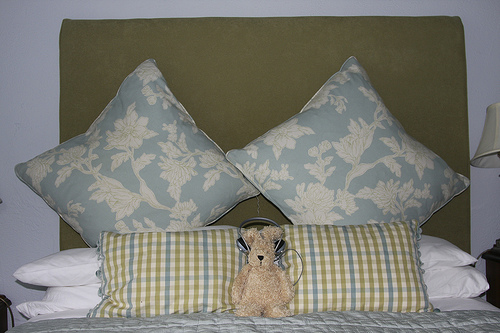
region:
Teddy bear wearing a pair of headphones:
[221, 210, 306, 322]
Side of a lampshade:
[462, 90, 499, 184]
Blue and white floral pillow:
[17, 63, 258, 267]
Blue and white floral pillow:
[217, 43, 481, 228]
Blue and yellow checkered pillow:
[94, 228, 429, 313]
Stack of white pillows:
[9, 249, 99, 327]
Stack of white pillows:
[419, 225, 495, 309]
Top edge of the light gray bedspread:
[0, 313, 498, 330]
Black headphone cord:
[280, 248, 317, 288]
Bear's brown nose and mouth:
[255, 251, 266, 265]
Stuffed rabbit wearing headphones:
[219, 212, 319, 328]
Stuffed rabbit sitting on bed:
[221, 210, 311, 330]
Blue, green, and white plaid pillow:
[113, 233, 226, 306]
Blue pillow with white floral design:
[287, 120, 416, 216]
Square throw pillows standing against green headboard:
[54, 18, 471, 223]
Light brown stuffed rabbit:
[228, 230, 298, 322]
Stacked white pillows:
[20, 249, 95, 316]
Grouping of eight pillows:
[12, 63, 497, 310]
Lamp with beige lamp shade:
[468, 104, 498, 169]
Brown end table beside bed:
[477, 242, 498, 308]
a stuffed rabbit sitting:
[233, 215, 304, 316]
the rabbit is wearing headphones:
[224, 215, 306, 282]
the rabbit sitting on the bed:
[4, 197, 496, 328]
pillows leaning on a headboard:
[21, 11, 477, 331]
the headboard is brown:
[57, 13, 481, 260]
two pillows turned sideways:
[7, 57, 475, 233]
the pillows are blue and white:
[13, 58, 468, 238]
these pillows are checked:
[97, 224, 436, 318]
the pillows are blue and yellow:
[97, 216, 427, 316]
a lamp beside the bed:
[467, 92, 499, 182]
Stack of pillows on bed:
[24, 95, 437, 327]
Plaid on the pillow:
[317, 253, 393, 283]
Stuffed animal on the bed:
[226, 218, 296, 326]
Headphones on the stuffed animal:
[230, 205, 296, 262]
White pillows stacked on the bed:
[18, 227, 78, 322]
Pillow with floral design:
[293, 100, 450, 222]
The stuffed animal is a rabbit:
[220, 213, 307, 330]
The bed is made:
[312, 298, 351, 329]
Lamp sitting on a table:
[463, 104, 495, 171]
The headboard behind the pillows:
[83, 22, 476, 97]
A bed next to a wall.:
[0, 0, 498, 331]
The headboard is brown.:
[55, 12, 472, 298]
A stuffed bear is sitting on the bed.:
[223, 206, 303, 319]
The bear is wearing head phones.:
[231, 215, 286, 267]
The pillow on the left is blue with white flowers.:
[10, 55, 260, 230]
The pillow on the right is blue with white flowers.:
[225, 45, 470, 235]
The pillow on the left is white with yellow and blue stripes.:
[96, 216, 241, 312]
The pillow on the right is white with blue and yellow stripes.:
[285, 222, 435, 309]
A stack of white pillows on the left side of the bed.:
[6, 240, 99, 321]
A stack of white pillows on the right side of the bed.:
[420, 228, 492, 306]